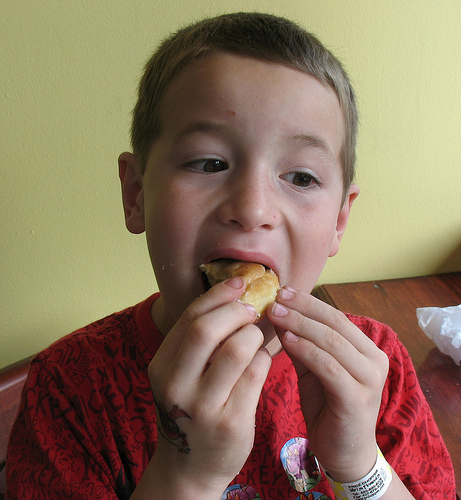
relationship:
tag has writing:
[309, 443, 397, 499] [347, 469, 387, 499]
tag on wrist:
[309, 443, 397, 499] [318, 445, 396, 500]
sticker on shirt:
[279, 438, 321, 493] [4, 290, 457, 498]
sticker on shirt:
[221, 483, 261, 499] [4, 290, 457, 498]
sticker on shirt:
[291, 491, 331, 499] [4, 290, 457, 498]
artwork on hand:
[148, 383, 193, 458] [135, 275, 273, 487]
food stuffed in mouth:
[197, 258, 281, 320] [196, 246, 284, 308]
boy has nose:
[6, 11, 457, 499] [215, 167, 286, 231]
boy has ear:
[6, 11, 457, 499] [115, 151, 145, 235]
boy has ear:
[6, 11, 457, 499] [329, 184, 362, 259]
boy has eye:
[6, 11, 457, 499] [183, 158, 229, 172]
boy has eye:
[6, 11, 457, 499] [278, 171, 319, 187]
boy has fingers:
[6, 11, 457, 499] [267, 285, 374, 393]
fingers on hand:
[267, 285, 374, 393] [264, 283, 391, 470]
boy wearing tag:
[6, 11, 457, 499] [309, 443, 397, 499]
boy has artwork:
[6, 11, 457, 499] [148, 383, 193, 458]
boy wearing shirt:
[6, 11, 457, 499] [4, 290, 457, 498]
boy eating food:
[6, 11, 457, 499] [197, 258, 281, 320]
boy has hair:
[6, 11, 457, 499] [127, 10, 359, 209]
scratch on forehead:
[227, 108, 237, 116] [165, 51, 347, 156]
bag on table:
[414, 303, 461, 365] [310, 270, 460, 499]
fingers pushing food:
[267, 285, 374, 393] [197, 258, 281, 320]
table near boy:
[310, 270, 460, 499] [6, 11, 457, 499]